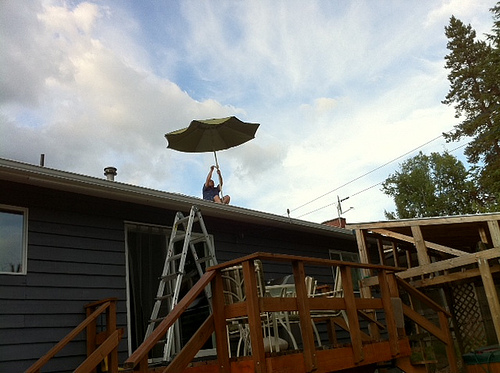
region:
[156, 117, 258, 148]
The top of the umbrella.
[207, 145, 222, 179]
The pole of the umbrella.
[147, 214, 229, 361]
The ladder on the deck.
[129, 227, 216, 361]
The door behind the ladder.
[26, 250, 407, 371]
The wooden deck of the house.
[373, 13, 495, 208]
The trees on the right.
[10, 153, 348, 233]
The roof of the house.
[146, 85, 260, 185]
this is an umbrella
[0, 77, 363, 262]
umbrella on a roof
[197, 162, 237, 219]
this is a person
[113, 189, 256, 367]
this is a ladder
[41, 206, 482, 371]
a wooden brown deck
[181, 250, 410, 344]
railing on the deck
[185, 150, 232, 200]
person holding umbrella pole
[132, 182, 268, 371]
the ladder is silver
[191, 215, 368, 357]
a outside patio table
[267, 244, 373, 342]
a white patio chair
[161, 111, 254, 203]
An open umbrella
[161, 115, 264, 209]
a man holding an open umbrella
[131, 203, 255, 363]
an aluminum step ladder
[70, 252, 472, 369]
a wooden back deck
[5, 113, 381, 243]
a man on a roof with an umbrella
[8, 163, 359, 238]
a man on a roof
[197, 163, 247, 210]
a large man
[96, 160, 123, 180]
a chimney cap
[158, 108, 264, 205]
man holding umbrella on roof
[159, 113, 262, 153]
open white large umbrella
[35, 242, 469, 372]
wooden deck with white ladder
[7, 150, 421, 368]
grey wooden house with white roof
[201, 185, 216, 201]
man is wearing blue shirt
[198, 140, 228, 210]
man is holding umbrella pole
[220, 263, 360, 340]
white chairs and table stacked on deck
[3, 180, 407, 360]
grey wooden siding on house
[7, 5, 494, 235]
blue sky with streaky clouds over roof and trees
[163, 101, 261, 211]
man holding large umbrella on roof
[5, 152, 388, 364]
white edge on top of house in dark siding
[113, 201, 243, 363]
metal ladder in front of dark sliding doors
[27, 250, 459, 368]
white dining set on brown wooden deck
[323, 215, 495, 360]
wooden framing for extension on side of house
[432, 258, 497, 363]
dark lattice panel under pieces of lumber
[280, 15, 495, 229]
electrical wires running over and behind trees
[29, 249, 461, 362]
railings and handrails on sides of outdoor deck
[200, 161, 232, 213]
man seated on top of roof with hands around pole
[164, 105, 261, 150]
a beige patio umbrella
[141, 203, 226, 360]
a tall metal utility ladder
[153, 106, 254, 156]
yellow umbrella on roof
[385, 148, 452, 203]
green and brown leaves in brown tree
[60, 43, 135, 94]
white clouds in the blue sky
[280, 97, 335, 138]
white clouds in the blue sky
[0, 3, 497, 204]
A light blue sky with large white clouds.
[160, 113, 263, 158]
A large sun umbrella.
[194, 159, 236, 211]
A person sitting on top of a roof.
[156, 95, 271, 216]
A person holding up an umbrella.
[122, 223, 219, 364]
Sliding glass doors.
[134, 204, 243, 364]
A silver ladder.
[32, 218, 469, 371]
A wooden back porch of a house.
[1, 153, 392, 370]
A blue and white house.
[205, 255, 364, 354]
A table with chairs on a porch.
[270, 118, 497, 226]
Powerlines.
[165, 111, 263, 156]
a green outdoor umbrella